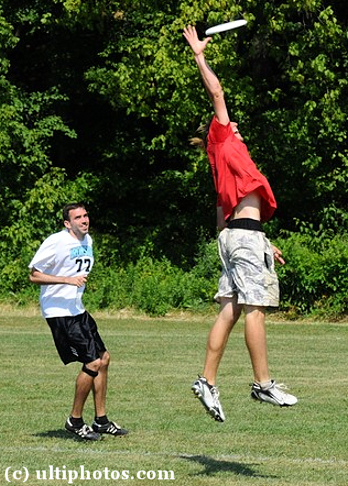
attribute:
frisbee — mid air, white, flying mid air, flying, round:
[207, 17, 249, 35]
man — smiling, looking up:
[27, 206, 129, 441]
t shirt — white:
[29, 230, 93, 320]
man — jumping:
[181, 21, 297, 421]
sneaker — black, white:
[64, 417, 100, 441]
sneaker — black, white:
[93, 420, 129, 438]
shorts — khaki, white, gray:
[212, 218, 282, 311]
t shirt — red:
[206, 117, 276, 223]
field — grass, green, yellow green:
[1, 313, 347, 483]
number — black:
[75, 256, 91, 275]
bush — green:
[189, 217, 344, 321]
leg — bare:
[203, 280, 241, 380]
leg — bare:
[233, 265, 270, 379]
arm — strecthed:
[195, 51, 229, 127]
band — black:
[81, 366, 99, 378]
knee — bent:
[91, 358, 104, 372]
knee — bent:
[103, 351, 112, 367]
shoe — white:
[191, 372, 226, 425]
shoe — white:
[248, 380, 299, 409]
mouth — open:
[233, 129, 241, 136]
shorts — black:
[45, 310, 109, 369]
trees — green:
[14, 3, 348, 271]